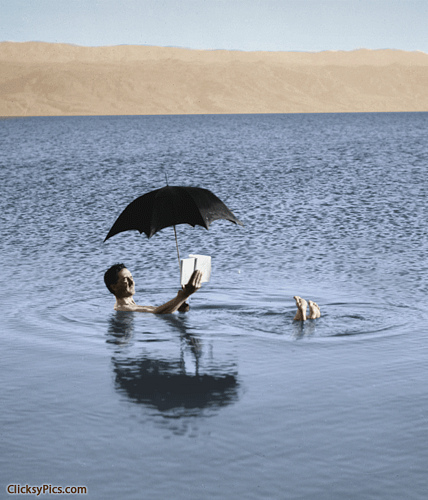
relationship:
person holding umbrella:
[104, 260, 323, 326] [103, 171, 240, 312]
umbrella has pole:
[103, 171, 240, 312] [163, 169, 181, 269]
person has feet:
[104, 260, 323, 326] [290, 293, 321, 327]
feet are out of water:
[290, 293, 321, 327] [2, 114, 423, 498]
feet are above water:
[290, 293, 321, 327] [2, 114, 423, 498]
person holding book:
[104, 260, 323, 326] [176, 252, 214, 292]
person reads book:
[104, 260, 323, 326] [176, 252, 214, 292]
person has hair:
[104, 260, 323, 326] [101, 260, 129, 298]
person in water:
[104, 260, 323, 326] [2, 114, 423, 498]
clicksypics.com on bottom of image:
[4, 480, 92, 498] [2, 3, 425, 499]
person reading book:
[104, 260, 323, 326] [176, 252, 214, 292]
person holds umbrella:
[104, 260, 323, 326] [103, 171, 240, 312]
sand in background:
[2, 40, 427, 117] [2, 27, 427, 131]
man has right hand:
[104, 260, 323, 326] [180, 268, 202, 298]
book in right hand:
[176, 252, 214, 292] [180, 268, 202, 298]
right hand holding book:
[180, 268, 202, 298] [176, 252, 214, 292]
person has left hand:
[104, 260, 323, 326] [176, 282, 188, 303]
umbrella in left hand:
[103, 171, 240, 312] [176, 282, 188, 303]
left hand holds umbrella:
[176, 282, 188, 303] [103, 171, 240, 312]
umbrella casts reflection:
[103, 171, 240, 312] [110, 336, 240, 424]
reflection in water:
[110, 336, 240, 424] [2, 114, 423, 498]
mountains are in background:
[2, 38, 427, 120] [2, 27, 427, 131]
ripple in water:
[315, 186, 403, 198] [2, 114, 423, 498]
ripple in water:
[0, 111, 427, 315] [2, 114, 423, 498]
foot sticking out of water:
[306, 297, 321, 321] [2, 114, 423, 498]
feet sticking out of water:
[293, 295, 309, 321] [2, 114, 423, 498]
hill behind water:
[2, 38, 427, 120] [2, 114, 423, 498]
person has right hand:
[104, 260, 323, 326] [180, 268, 202, 298]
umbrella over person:
[103, 171, 240, 312] [104, 260, 323, 326]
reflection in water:
[107, 329, 244, 439] [2, 114, 423, 498]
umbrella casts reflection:
[103, 171, 240, 312] [107, 329, 244, 439]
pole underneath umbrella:
[163, 169, 181, 269] [103, 171, 240, 312]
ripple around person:
[36, 282, 427, 348] [104, 260, 323, 326]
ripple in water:
[36, 282, 427, 348] [2, 114, 423, 498]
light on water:
[5, 274, 426, 448] [2, 114, 423, 498]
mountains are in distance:
[2, 38, 427, 120] [5, 3, 427, 163]